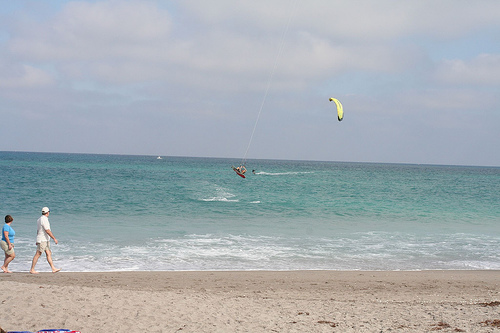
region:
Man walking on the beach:
[26, 203, 63, 269]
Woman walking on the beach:
[3, 215, 17, 270]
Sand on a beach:
[73, 253, 498, 331]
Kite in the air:
[320, 86, 352, 127]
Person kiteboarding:
[223, 160, 255, 184]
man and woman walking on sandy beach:
[3, 266, 497, 328]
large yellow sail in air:
[323, 92, 348, 126]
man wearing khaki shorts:
[36, 243, 52, 257]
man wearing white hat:
[39, 204, 49, 211]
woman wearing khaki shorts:
[2, 240, 13, 253]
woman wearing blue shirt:
[1, 223, 17, 243]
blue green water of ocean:
[1, 149, 498, 267]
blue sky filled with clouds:
[0, 5, 499, 161]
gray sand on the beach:
[139, 275, 248, 302]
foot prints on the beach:
[288, 292, 342, 325]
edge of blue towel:
[33, 316, 71, 331]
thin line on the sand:
[244, 282, 439, 313]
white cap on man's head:
[29, 201, 55, 213]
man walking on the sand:
[28, 194, 85, 294]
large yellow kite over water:
[322, 70, 367, 134]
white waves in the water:
[251, 156, 342, 185]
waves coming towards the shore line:
[132, 223, 296, 273]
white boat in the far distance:
[140, 143, 181, 170]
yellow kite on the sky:
[321, 87, 354, 129]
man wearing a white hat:
[38, 203, 52, 213]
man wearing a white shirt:
[32, 215, 55, 242]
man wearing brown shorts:
[33, 238, 53, 253]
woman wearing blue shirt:
[4, 221, 14, 243]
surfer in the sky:
[230, 163, 255, 184]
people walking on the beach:
[3, 196, 63, 275]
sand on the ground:
[161, 277, 293, 331]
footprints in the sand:
[81, 270, 311, 329]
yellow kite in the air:
[321, 83, 347, 128]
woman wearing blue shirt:
[0, 213, 22, 273]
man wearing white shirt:
[26, 202, 58, 271]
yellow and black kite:
[327, 95, 347, 125]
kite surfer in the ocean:
[229, 162, 250, 179]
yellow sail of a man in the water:
[328, 95, 343, 121]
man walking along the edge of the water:
[27, 205, 58, 273]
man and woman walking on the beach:
[2, 203, 59, 273]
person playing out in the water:
[233, 163, 248, 178]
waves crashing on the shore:
[0, 233, 495, 273]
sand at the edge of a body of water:
[3, 270, 498, 330]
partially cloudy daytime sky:
[4, 2, 497, 167]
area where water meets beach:
[5, 241, 498, 283]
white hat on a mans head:
[41, 205, 48, 213]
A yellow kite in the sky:
[304, 65, 413, 182]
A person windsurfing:
[223, 147, 308, 206]